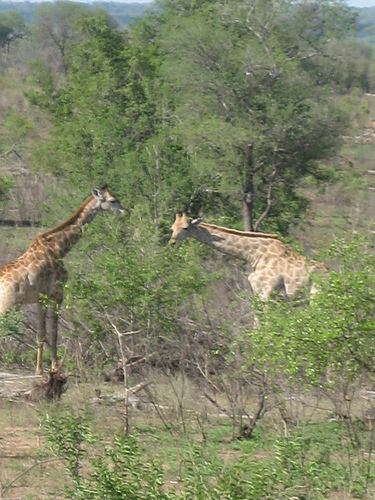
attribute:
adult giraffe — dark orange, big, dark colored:
[8, 172, 146, 422]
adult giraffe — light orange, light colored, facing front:
[157, 189, 369, 410]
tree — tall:
[139, 5, 317, 368]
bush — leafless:
[137, 292, 298, 436]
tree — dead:
[110, 308, 373, 427]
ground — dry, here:
[0, 376, 356, 475]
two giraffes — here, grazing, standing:
[5, 177, 352, 405]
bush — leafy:
[228, 226, 370, 411]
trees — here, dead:
[0, 7, 367, 315]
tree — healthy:
[32, 15, 224, 316]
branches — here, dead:
[87, 300, 161, 416]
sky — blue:
[19, 1, 168, 28]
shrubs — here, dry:
[50, 415, 364, 500]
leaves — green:
[236, 259, 369, 399]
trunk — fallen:
[34, 364, 75, 413]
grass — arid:
[9, 417, 236, 480]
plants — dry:
[97, 290, 305, 439]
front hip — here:
[286, 255, 334, 290]